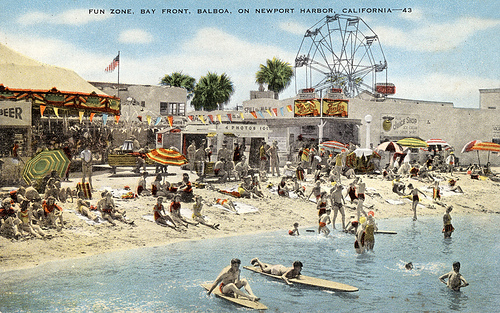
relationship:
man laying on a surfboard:
[250, 254, 304, 287] [244, 263, 363, 294]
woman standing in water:
[351, 221, 368, 258] [1, 216, 500, 313]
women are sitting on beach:
[153, 194, 223, 232] [1, 161, 500, 270]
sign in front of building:
[379, 112, 419, 140] [186, 79, 499, 180]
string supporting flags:
[35, 103, 293, 114] [35, 105, 294, 129]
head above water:
[404, 260, 415, 274] [1, 216, 500, 313]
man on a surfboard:
[250, 254, 304, 287] [244, 263, 363, 294]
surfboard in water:
[244, 263, 363, 294] [1, 216, 500, 313]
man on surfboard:
[250, 254, 304, 287] [244, 263, 363, 294]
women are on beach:
[153, 194, 223, 232] [1, 161, 500, 270]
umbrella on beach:
[147, 146, 187, 183] [1, 161, 500, 270]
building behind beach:
[186, 79, 499, 180] [1, 161, 500, 270]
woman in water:
[351, 221, 368, 258] [1, 216, 500, 313]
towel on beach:
[216, 199, 259, 216] [1, 161, 500, 270]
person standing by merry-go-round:
[79, 143, 94, 186] [1, 39, 125, 158]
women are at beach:
[153, 194, 223, 232] [1, 161, 500, 270]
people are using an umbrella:
[134, 169, 196, 199] [147, 146, 187, 183]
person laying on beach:
[212, 192, 241, 212] [1, 161, 500, 270]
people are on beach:
[134, 169, 196, 199] [1, 161, 500, 270]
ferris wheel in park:
[293, 12, 394, 99] [5, 31, 465, 309]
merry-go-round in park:
[1, 39, 125, 158] [1, 14, 498, 310]